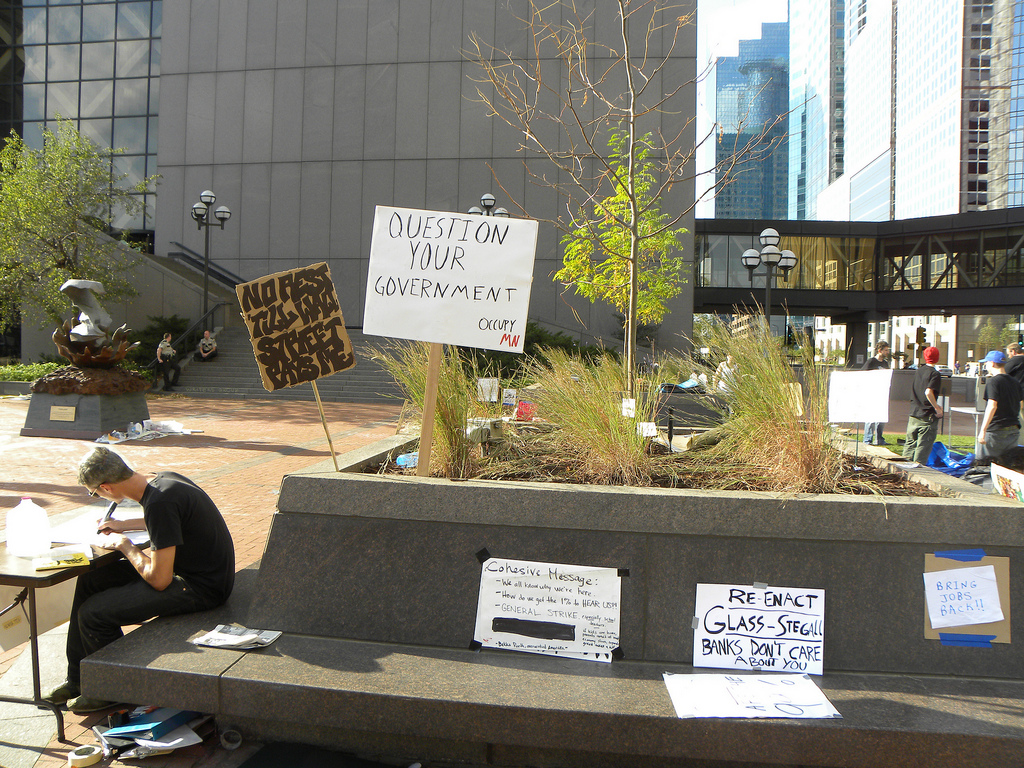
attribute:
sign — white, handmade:
[342, 193, 556, 359]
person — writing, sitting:
[39, 437, 240, 718]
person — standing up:
[974, 344, 1018, 455]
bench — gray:
[78, 494, 1019, 767]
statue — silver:
[38, 271, 126, 364]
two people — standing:
[898, 330, 1016, 487]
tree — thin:
[452, 8, 824, 402]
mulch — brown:
[371, 436, 937, 491]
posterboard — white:
[355, 199, 528, 471]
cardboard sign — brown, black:
[218, 254, 353, 432]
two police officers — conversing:
[152, 326, 226, 395]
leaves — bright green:
[554, 236, 606, 291]